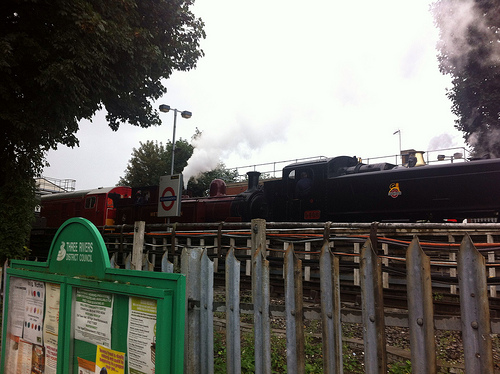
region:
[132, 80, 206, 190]
street lamps turned off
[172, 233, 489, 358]
row of metal poles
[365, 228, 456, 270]
red, black, and white cables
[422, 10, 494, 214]
steam from the train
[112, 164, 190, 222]
red, black and white sign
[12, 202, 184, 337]
a green message board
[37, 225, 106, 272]
letters written in white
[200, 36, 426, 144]
the sky is cloudy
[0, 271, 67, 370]
white pieces of paper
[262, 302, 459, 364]
rocks on the ground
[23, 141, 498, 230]
Train going down a track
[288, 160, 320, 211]
Conductor on the train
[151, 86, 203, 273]
Light pole with two lamps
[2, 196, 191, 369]
Green board that holds posters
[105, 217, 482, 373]
Old metal fence rail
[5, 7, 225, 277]
Large tree near train track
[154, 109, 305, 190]
Smoke coming out of train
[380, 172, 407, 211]
Sign on black train car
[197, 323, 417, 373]
Grass seen through fence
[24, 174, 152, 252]
Red train car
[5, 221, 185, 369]
green sign with posters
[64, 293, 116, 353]
green and white poster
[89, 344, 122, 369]
yellow and red poster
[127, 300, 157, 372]
white and yellow poster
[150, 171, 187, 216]
white sign with red circle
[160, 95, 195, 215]
tall streetlight with two lights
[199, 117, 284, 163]
white smoke in air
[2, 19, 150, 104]
tree with leaves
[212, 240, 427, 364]
old brown wooden fence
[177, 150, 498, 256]
train behind fence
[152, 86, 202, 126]
the lights are off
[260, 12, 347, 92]
the sky is white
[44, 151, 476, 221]
the train is red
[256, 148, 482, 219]
the train is black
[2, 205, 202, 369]
the billboard is green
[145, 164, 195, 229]
the sign is red and white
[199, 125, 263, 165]
the smoke is coming from the train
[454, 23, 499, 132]
the tree is behind some smoke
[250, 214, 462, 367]
the fence is short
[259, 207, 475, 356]
the fence is metal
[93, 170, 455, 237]
The train is on the track.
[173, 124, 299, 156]
Steam coming from the train.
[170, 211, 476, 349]
A gate blocking off the tracks.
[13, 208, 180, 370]
A green guide sign posted by the railing.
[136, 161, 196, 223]
A white sign on the light pole.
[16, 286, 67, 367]
Paper posted on the guide board.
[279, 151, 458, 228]
The man train is black.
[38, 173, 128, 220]
the train car is red.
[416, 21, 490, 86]
The steam from the train is by the tree.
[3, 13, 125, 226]
the tree is next to the train.